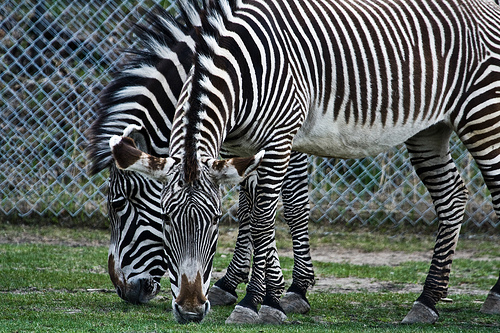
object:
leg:
[237, 133, 288, 326]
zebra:
[111, 5, 497, 315]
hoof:
[481, 290, 496, 315]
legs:
[279, 147, 317, 315]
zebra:
[108, 0, 499, 329]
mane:
[83, 0, 203, 165]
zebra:
[84, 0, 315, 311]